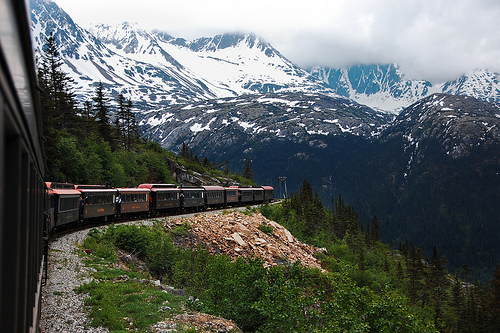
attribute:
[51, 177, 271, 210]
train — long, black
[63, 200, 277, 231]
track — curved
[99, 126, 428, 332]
mountain — covered, steep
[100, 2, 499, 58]
clouds — dense, grey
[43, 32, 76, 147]
tree — tall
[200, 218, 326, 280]
rocks — brown, yellow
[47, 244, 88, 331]
gravels — grey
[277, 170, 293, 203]
structure — tall, wood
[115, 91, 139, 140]
trees — tall, green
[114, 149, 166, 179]
bushes — short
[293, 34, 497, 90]
cloud — low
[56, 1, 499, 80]
sky — grey, cloudy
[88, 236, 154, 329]
grass — green, short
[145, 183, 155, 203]
corner — red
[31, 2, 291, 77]
mountains — black